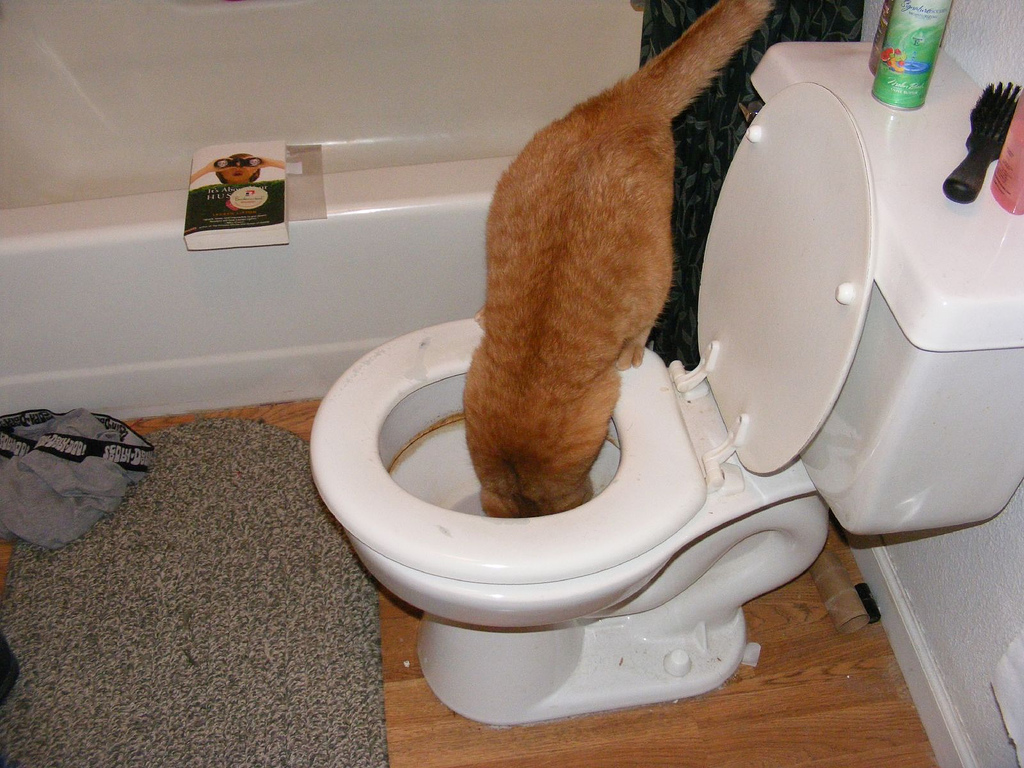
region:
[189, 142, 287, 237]
Book on edge of bathtub.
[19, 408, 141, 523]
Gray shorts on floor.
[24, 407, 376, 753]
Gray rug sitting on floor.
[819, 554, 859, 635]
Empty toilet paper roll behind toilet.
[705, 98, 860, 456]
White toilet lid is up.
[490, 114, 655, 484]
Cat standing on toilet is orange.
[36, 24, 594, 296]
White bathtub is in room.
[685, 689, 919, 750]
Floor in bathroom is light brown.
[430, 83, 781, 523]
Cat drinking from toilet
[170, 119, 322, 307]
Book sitting on edge of bathtub.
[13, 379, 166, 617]
Grey colored boxers near bathtub.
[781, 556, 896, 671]
Empty roll of toilet paper behind toilet.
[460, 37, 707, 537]
Orange tabby cat with head in toilet.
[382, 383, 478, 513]
Brown rusty ring around toilet bowl.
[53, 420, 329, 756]
Grey and black rug near toilet.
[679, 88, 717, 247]
Black and grey colored shower curtain.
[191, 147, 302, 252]
Book on side of tub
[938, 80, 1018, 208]
Black brush on toilet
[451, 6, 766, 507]
Cat head first in toilet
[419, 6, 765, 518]
Brown cat in toilet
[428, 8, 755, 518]
Cat is brown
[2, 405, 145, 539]
Gray and black underwear on floor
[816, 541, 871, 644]
Empty toilet roll on floor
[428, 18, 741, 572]
cat inside the toilet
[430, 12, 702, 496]
cat drinking water from the toilet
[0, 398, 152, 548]
underwear on the bathroom floor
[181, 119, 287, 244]
book on the side of the tub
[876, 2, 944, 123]
air freshner on the back of the toilet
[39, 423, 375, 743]
rug on bathroom floor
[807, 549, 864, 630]
empty toilet paper roll on the floor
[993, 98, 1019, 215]
pink liquid on the back of the toilet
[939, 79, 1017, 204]
A plain black hair brush.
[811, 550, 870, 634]
A cylindrical paper roll.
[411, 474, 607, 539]
Cats' head is inside the bowl.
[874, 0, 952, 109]
A green bottle of air freshener.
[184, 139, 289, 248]
A book on top of the tub.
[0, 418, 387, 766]
A gray floor mat.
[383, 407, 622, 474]
An orange stain around the toilet bowl.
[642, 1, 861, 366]
A black with green designs curtain.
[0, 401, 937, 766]
A brown and wooden floor.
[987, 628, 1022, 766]
A piece of tissue paper hanging.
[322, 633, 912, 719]
A panel on the floor.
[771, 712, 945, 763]
A panel on the floor.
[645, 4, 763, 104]
Tail of a cat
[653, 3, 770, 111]
Orange tail of a cat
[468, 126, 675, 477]
Body of a cat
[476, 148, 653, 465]
Body of a orange cat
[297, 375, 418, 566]
Top of a toilet seat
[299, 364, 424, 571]
Top of a white toilet seat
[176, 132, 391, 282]
Book on a bath tub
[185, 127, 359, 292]
Book on a white bath tub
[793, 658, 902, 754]
Section of the hardwood floor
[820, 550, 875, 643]
empty toilet paper roll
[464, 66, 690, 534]
cat drinking from toilet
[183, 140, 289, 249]
book with a person looking through binoculars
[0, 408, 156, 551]
dirty gray boxers on the rug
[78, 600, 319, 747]
light brown shag rug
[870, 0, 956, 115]
green air freshener can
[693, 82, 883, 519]
toilet seat lid in the up position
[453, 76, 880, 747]
a cat int he toilet